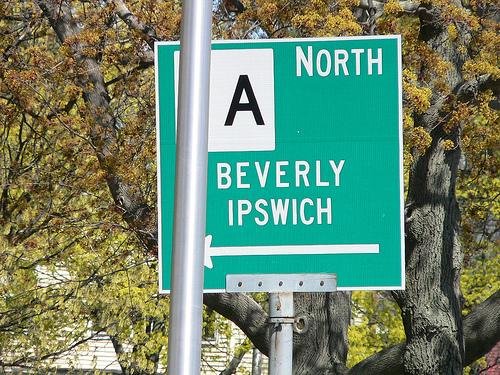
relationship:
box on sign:
[171, 50, 279, 152] [151, 35, 408, 292]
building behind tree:
[3, 234, 270, 375] [1, 1, 499, 374]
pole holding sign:
[266, 291, 297, 374] [151, 35, 408, 292]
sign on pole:
[151, 35, 408, 292] [266, 291, 297, 374]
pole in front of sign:
[164, 1, 213, 375] [151, 35, 408, 292]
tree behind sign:
[1, 1, 499, 374] [151, 35, 408, 292]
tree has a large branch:
[1, 1, 499, 374] [37, 3, 273, 355]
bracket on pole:
[227, 273, 339, 293] [266, 291, 297, 374]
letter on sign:
[216, 162, 232, 191] [151, 35, 408, 292]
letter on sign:
[235, 162, 252, 190] [151, 35, 408, 292]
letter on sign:
[254, 162, 272, 189] [151, 35, 408, 292]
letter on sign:
[276, 160, 291, 190] [151, 35, 408, 292]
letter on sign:
[294, 160, 311, 188] [151, 35, 408, 292]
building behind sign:
[3, 234, 270, 375] [151, 35, 408, 292]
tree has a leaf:
[1, 1, 499, 374] [66, 31, 85, 45]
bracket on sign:
[227, 273, 339, 293] [151, 35, 408, 292]